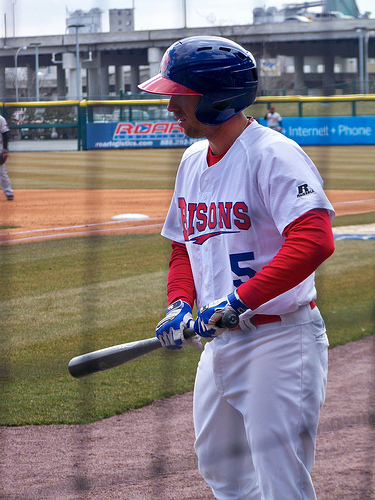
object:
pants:
[192, 300, 329, 499]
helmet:
[137, 34, 260, 126]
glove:
[156, 299, 195, 349]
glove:
[193, 289, 249, 338]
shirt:
[160, 117, 336, 322]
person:
[136, 35, 336, 496]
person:
[0, 115, 14, 201]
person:
[263, 104, 283, 140]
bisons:
[177, 197, 251, 246]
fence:
[7, 109, 375, 153]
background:
[1, 1, 373, 150]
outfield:
[1, 3, 369, 465]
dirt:
[0, 335, 374, 500]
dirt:
[0, 188, 374, 246]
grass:
[0, 210, 374, 427]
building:
[106, 8, 141, 35]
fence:
[0, 93, 375, 108]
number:
[229, 251, 257, 288]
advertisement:
[95, 122, 206, 147]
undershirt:
[164, 113, 335, 312]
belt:
[225, 301, 318, 332]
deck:
[5, 21, 370, 116]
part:
[136, 73, 202, 96]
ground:
[0, 145, 375, 499]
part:
[0, 152, 16, 198]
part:
[1, 221, 21, 231]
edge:
[67, 335, 162, 368]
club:
[67, 324, 203, 386]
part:
[6, 155, 15, 172]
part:
[306, 297, 318, 309]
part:
[1, 117, 17, 151]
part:
[0, 115, 10, 132]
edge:
[136, 85, 202, 96]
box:
[0, 188, 173, 243]